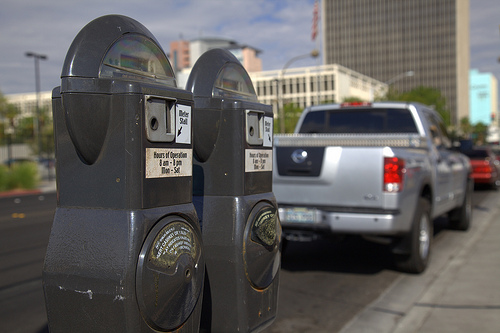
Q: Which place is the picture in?
A: It is at the street.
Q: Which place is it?
A: It is a street.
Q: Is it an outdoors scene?
A: Yes, it is outdoors.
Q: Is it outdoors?
A: Yes, it is outdoors.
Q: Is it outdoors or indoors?
A: It is outdoors.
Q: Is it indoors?
A: No, it is outdoors.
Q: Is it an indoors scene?
A: No, it is outdoors.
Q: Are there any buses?
A: No, there are no buses.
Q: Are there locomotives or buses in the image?
A: No, there are no buses or locomotives.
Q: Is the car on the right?
A: Yes, the car is on the right of the image.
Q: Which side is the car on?
A: The car is on the right of the image.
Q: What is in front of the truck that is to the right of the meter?
A: The car is in front of the truck.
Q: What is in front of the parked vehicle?
A: The car is in front of the truck.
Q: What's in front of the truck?
A: The car is in front of the truck.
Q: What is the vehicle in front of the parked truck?
A: The vehicle is a car.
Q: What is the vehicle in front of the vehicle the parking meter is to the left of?
A: The vehicle is a car.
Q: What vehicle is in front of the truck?
A: The vehicle is a car.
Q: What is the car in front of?
A: The car is in front of the truck.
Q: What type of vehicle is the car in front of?
A: The car is in front of the truck.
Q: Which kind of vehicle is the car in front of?
A: The car is in front of the truck.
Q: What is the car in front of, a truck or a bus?
A: The car is in front of a truck.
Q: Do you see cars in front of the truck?
A: Yes, there is a car in front of the truck.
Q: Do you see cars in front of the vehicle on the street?
A: Yes, there is a car in front of the truck.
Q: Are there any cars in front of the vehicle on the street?
A: Yes, there is a car in front of the truck.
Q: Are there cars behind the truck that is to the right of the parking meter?
A: No, the car is in front of the truck.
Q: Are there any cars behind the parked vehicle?
A: No, the car is in front of the truck.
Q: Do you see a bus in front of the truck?
A: No, there is a car in front of the truck.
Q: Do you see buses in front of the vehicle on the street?
A: No, there is a car in front of the truck.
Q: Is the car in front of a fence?
A: No, the car is in front of a truck.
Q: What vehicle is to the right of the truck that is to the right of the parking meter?
A: The vehicle is a car.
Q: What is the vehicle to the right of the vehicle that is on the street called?
A: The vehicle is a car.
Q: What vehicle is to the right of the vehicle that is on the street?
A: The vehicle is a car.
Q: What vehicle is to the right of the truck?
A: The vehicle is a car.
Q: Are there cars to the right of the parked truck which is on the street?
A: Yes, there is a car to the right of the truck.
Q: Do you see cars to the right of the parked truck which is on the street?
A: Yes, there is a car to the right of the truck.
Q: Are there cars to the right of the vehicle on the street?
A: Yes, there is a car to the right of the truck.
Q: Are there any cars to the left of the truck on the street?
A: No, the car is to the right of the truck.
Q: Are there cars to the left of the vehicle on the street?
A: No, the car is to the right of the truck.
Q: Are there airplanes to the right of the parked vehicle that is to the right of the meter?
A: No, there is a car to the right of the truck.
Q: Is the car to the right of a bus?
A: No, the car is to the right of a truck.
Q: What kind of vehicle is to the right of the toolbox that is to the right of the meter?
A: The vehicle is a car.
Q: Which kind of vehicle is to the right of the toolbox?
A: The vehicle is a car.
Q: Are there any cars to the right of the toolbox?
A: Yes, there is a car to the right of the toolbox.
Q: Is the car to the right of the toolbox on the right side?
A: Yes, the car is to the right of the toolbox.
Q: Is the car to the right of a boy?
A: No, the car is to the right of the toolbox.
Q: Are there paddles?
A: No, there are no paddles.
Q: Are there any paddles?
A: No, there are no paddles.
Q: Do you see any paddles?
A: No, there are no paddles.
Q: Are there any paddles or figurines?
A: No, there are no paddles or figurines.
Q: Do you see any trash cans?
A: No, there are no trash cans.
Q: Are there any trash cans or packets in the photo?
A: No, there are no trash cans or packets.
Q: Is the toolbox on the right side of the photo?
A: Yes, the toolbox is on the right of the image.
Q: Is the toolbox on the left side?
A: No, the toolbox is on the right of the image.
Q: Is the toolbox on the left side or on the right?
A: The toolbox is on the right of the image.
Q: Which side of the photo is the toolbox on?
A: The toolbox is on the right of the image.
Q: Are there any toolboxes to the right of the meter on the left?
A: Yes, there is a toolbox to the right of the meter.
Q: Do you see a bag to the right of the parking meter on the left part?
A: No, there is a toolbox to the right of the meter.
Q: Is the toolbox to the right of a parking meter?
A: Yes, the toolbox is to the right of a parking meter.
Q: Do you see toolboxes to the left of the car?
A: Yes, there is a toolbox to the left of the car.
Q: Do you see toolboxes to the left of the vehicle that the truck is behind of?
A: Yes, there is a toolbox to the left of the car.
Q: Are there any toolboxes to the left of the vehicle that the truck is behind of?
A: Yes, there is a toolbox to the left of the car.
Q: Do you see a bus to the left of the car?
A: No, there is a toolbox to the left of the car.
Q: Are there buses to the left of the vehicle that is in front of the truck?
A: No, there is a toolbox to the left of the car.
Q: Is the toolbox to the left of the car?
A: Yes, the toolbox is to the left of the car.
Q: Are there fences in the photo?
A: No, there are no fences.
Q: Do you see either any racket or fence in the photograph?
A: No, there are no fences or rackets.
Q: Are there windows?
A: Yes, there is a window.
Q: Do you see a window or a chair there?
A: Yes, there is a window.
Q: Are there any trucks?
A: Yes, there is a truck.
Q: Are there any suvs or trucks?
A: Yes, there is a truck.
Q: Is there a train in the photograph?
A: No, there are no trains.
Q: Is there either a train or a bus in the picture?
A: No, there are no trains or buses.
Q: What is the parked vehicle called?
A: The vehicle is a truck.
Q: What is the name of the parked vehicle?
A: The vehicle is a truck.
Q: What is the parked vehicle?
A: The vehicle is a truck.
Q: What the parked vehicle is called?
A: The vehicle is a truck.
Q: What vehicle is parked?
A: The vehicle is a truck.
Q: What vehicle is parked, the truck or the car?
A: The truck is parked.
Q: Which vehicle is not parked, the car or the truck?
A: The car is not parked.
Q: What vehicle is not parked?
A: The vehicle is a car.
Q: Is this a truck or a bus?
A: This is a truck.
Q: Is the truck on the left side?
A: No, the truck is on the right of the image.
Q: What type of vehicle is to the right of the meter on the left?
A: The vehicle is a truck.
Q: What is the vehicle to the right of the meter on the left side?
A: The vehicle is a truck.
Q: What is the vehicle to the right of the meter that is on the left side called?
A: The vehicle is a truck.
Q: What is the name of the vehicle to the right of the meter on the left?
A: The vehicle is a truck.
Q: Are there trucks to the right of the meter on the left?
A: Yes, there is a truck to the right of the parking meter.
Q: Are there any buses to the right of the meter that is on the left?
A: No, there is a truck to the right of the parking meter.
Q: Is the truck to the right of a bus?
A: No, the truck is to the right of the meter.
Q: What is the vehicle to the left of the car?
A: The vehicle is a truck.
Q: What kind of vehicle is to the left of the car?
A: The vehicle is a truck.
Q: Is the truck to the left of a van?
A: No, the truck is to the left of the car.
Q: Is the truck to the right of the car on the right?
A: No, the truck is to the left of the car.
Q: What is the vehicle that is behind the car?
A: The vehicle is a truck.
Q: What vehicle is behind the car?
A: The vehicle is a truck.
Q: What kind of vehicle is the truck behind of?
A: The truck is behind the car.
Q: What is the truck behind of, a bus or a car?
A: The truck is behind a car.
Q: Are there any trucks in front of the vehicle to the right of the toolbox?
A: No, the truck is behind the car.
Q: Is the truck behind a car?
A: Yes, the truck is behind a car.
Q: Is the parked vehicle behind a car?
A: Yes, the truck is behind a car.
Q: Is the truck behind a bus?
A: No, the truck is behind a car.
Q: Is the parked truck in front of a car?
A: No, the truck is behind a car.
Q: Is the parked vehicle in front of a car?
A: No, the truck is behind a car.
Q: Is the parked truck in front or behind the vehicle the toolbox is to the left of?
A: The truck is behind the car.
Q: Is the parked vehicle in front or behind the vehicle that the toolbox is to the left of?
A: The truck is behind the car.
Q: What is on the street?
A: The truck is on the street.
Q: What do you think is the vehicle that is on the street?
A: The vehicle is a truck.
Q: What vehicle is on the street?
A: The vehicle is a truck.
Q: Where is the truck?
A: The truck is on the street.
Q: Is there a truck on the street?
A: Yes, there is a truck on the street.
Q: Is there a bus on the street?
A: No, there is a truck on the street.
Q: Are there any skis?
A: No, there are no skis.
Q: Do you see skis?
A: No, there are no skis.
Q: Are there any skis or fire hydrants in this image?
A: No, there are no skis or fire hydrants.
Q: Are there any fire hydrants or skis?
A: No, there are no skis or fire hydrants.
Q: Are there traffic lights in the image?
A: No, there are no traffic lights.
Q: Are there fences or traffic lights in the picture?
A: No, there are no traffic lights or fences.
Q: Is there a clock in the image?
A: No, there are no clocks.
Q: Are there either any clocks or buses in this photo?
A: No, there are no clocks or buses.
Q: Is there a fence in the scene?
A: No, there are no fences.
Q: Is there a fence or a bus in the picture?
A: No, there are no fences or buses.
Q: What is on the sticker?
A: The sign is on the sticker.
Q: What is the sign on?
A: The sign is on the sticker.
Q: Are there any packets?
A: No, there are no packets.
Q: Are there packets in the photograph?
A: No, there are no packets.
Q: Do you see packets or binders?
A: No, there are no packets or binders.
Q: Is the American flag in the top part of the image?
A: Yes, the American flag is in the top of the image.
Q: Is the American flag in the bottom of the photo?
A: No, the American flag is in the top of the image.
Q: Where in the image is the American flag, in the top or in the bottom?
A: The American flag is in the top of the image.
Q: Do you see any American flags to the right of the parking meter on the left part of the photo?
A: Yes, there is an American flag to the right of the meter.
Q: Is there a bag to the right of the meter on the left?
A: No, there is an American flag to the right of the parking meter.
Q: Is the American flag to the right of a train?
A: No, the American flag is to the right of the parking meter.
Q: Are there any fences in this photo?
A: No, there are no fences.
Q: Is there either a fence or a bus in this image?
A: No, there are no fences or buses.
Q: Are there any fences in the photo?
A: No, there are no fences.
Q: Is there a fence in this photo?
A: No, there are no fences.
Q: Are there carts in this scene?
A: No, there are no carts.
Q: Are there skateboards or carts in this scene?
A: No, there are no carts or skateboards.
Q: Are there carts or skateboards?
A: No, there are no carts or skateboards.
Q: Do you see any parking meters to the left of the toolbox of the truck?
A: Yes, there is a parking meter to the left of the toolbox.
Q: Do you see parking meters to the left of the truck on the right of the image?
A: Yes, there is a parking meter to the left of the truck.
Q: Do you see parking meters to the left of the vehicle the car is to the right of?
A: Yes, there is a parking meter to the left of the truck.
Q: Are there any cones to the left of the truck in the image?
A: No, there is a parking meter to the left of the truck.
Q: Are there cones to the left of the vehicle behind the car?
A: No, there is a parking meter to the left of the truck.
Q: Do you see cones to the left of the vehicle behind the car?
A: No, there is a parking meter to the left of the truck.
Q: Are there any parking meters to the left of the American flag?
A: Yes, there is a parking meter to the left of the American flag.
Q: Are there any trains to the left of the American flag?
A: No, there is a parking meter to the left of the American flag.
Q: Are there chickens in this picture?
A: No, there are no chickens.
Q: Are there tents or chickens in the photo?
A: No, there are no chickens or tents.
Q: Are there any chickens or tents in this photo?
A: No, there are no chickens or tents.